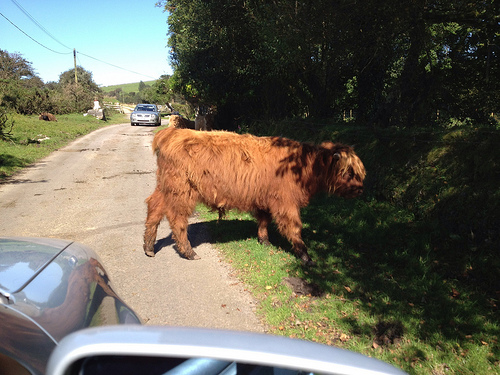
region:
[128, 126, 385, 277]
Large animal standing in the road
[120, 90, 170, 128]
Silver car on a road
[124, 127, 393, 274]
Shaggy brown cow standing in the road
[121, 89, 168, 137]
Silver car driving on a road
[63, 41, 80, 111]
Large wooden power pole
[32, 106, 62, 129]
Brown cow lying in the grass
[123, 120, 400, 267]
Brown cow walking across the road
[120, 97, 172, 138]
Silver car waiting for a cow to cross the road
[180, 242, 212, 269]
Large brown cow hoof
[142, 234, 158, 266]
Large brown cow hoof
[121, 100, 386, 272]
a very hairy cow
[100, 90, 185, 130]
a silver car driving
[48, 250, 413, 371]
a side view mirror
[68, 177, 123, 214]
a slab of concrete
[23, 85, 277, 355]
the gray concrete road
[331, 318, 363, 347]
a dead brown leaf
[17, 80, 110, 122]
a bunch of bushes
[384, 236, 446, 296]
a patch of grass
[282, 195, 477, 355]
a shady patch of grass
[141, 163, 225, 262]
a cow's back legs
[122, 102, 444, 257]
brown cow crossing the road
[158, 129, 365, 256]
this is a bull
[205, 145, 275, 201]
the fur is rugged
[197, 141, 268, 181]
the fur is brown in color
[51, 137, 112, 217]
this is the road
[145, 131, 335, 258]
the bull is walking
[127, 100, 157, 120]
this is a car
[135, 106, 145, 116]
the car is grey in color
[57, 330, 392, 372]
this is a side mirror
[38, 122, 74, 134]
this is the grass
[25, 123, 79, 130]
the grass is green in color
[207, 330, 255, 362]
edge of a side mirror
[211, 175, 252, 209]
stomach of a cow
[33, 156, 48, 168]
edge of the road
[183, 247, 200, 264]
hoof of a cow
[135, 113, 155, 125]
front of a car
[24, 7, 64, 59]
part of some wires